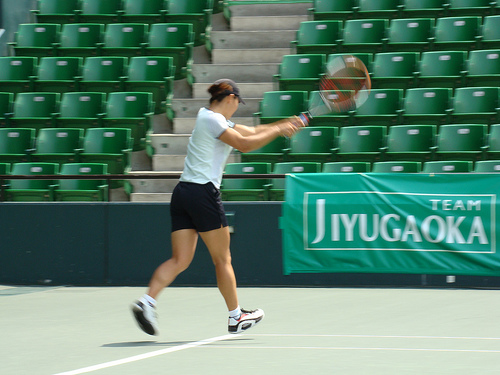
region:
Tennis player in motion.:
[125, 46, 373, 345]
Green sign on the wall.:
[275, 169, 499, 279]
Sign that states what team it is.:
[300, 183, 498, 258]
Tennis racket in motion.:
[296, 45, 375, 132]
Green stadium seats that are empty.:
[1, 4, 496, 207]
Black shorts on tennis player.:
[166, 173, 232, 238]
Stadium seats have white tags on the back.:
[2, 2, 499, 199]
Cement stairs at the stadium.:
[126, 0, 317, 206]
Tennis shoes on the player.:
[128, 282, 270, 346]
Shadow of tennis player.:
[100, 324, 260, 359]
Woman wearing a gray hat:
[207, 77, 247, 105]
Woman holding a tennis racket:
[288, 58, 376, 128]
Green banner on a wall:
[277, 166, 499, 281]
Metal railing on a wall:
[3, 173, 289, 180]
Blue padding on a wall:
[3, 202, 499, 290]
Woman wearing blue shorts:
[165, 180, 228, 233]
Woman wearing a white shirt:
[177, 108, 236, 186]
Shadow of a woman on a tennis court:
[98, 340, 205, 348]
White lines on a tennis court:
[41, 328, 498, 371]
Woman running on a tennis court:
[127, 73, 379, 366]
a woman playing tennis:
[134, 56, 369, 334]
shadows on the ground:
[104, 336, 246, 346]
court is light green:
[1, 285, 498, 373]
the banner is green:
[282, 175, 498, 275]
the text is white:
[304, 190, 495, 254]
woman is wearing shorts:
[170, 180, 225, 235]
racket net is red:
[322, 65, 362, 103]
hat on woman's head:
[208, 79, 243, 104]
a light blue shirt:
[180, 106, 232, 187]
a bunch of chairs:
[1, 0, 497, 199]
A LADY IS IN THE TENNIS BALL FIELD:
[151, 108, 331, 295]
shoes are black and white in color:
[131, 284, 298, 366]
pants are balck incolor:
[143, 167, 243, 248]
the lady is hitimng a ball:
[184, 94, 311, 281]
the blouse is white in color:
[167, 111, 259, 204]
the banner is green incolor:
[329, 188, 496, 279]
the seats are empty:
[403, 54, 486, 156]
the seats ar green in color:
[408, 109, 498, 174]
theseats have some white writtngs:
[392, 117, 484, 182]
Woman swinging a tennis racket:
[126, 55, 369, 335]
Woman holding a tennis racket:
[130, 53, 372, 338]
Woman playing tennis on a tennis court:
[130, 53, 371, 336]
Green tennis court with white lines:
[1, 283, 498, 373]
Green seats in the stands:
[1, 0, 498, 200]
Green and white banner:
[277, 170, 497, 277]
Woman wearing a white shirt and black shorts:
[128, 70, 304, 339]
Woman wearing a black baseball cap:
[130, 78, 308, 340]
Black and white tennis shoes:
[127, 293, 265, 340]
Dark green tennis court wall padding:
[0, 200, 499, 292]